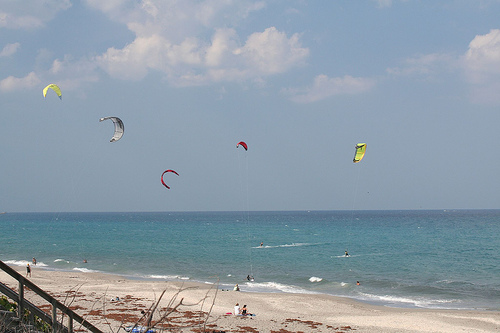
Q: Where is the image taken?
A: Near to beach.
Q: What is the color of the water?
A: Blue.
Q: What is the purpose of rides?
A: Enjoyment.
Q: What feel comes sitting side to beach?
A: Relaxation.